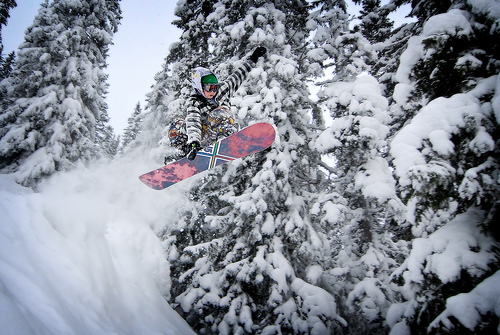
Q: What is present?
A: A player.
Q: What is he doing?
A: Ice skating.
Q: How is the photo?
A: Clear.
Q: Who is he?
A: A sportsman.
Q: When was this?
A: Daytime.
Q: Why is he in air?
A: Doing a stunt.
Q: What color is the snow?
A: White.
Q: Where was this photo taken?
A: In the snow.